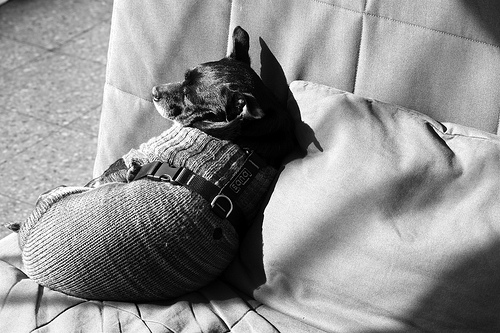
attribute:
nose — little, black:
[140, 71, 202, 120]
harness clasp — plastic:
[134, 159, 207, 190]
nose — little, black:
[141, 77, 201, 115]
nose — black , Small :
[131, 50, 221, 142]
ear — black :
[197, 22, 309, 112]